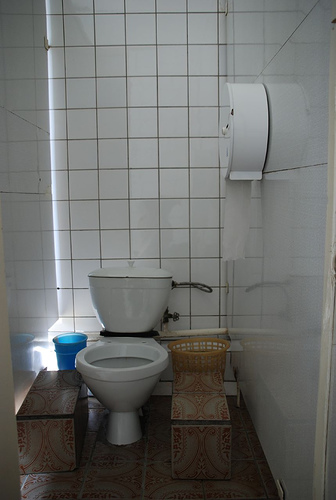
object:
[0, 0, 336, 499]
bathroom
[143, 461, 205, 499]
tile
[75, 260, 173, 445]
toilet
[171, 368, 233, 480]
shelf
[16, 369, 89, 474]
shelf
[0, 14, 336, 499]
wall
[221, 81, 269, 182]
toilet paper holder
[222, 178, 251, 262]
toilet paper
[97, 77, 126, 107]
tile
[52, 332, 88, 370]
bucket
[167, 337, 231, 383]
basket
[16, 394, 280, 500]
floor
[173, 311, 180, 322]
knob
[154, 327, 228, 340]
pipe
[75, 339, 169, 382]
toilet seat